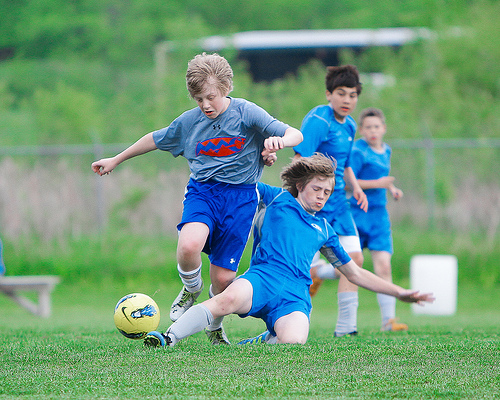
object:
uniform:
[234, 180, 354, 338]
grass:
[0, 221, 499, 400]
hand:
[263, 135, 283, 152]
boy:
[88, 51, 303, 348]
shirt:
[152, 94, 287, 187]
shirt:
[248, 180, 350, 287]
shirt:
[291, 104, 358, 192]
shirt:
[343, 139, 393, 206]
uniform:
[150, 95, 289, 272]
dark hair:
[322, 66, 361, 97]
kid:
[303, 107, 409, 333]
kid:
[291, 62, 371, 337]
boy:
[142, 147, 437, 350]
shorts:
[230, 260, 310, 336]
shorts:
[308, 190, 359, 239]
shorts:
[345, 194, 395, 254]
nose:
[200, 97, 210, 109]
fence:
[0, 119, 499, 261]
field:
[0, 227, 499, 399]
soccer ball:
[110, 292, 162, 341]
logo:
[228, 255, 238, 265]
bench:
[0, 274, 54, 316]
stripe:
[233, 181, 262, 273]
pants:
[173, 175, 263, 274]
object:
[406, 253, 456, 317]